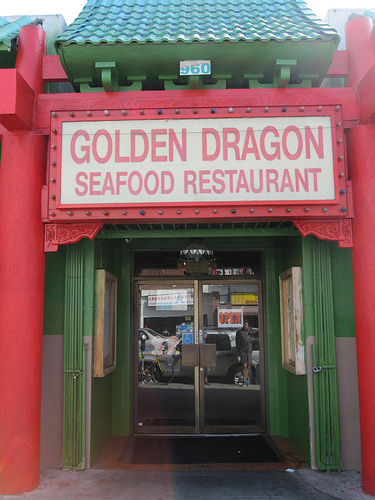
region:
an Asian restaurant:
[29, 75, 349, 301]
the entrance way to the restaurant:
[118, 255, 294, 470]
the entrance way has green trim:
[52, 207, 344, 439]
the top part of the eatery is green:
[52, 1, 362, 133]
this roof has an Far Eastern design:
[30, 8, 373, 172]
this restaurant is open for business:
[186, 287, 274, 366]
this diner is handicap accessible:
[138, 308, 228, 378]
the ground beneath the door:
[44, 449, 338, 498]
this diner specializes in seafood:
[66, 158, 338, 224]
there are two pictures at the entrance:
[87, 249, 314, 439]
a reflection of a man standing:
[233, 320, 254, 386]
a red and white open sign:
[217, 309, 245, 326]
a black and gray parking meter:
[139, 331, 147, 382]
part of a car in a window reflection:
[138, 328, 172, 350]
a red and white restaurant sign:
[46, 103, 349, 215]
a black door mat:
[126, 429, 285, 468]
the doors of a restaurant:
[137, 279, 270, 430]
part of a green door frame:
[305, 237, 343, 473]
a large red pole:
[0, 131, 60, 496]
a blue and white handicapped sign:
[180, 331, 193, 344]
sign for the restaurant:
[51, 114, 344, 210]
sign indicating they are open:
[217, 306, 251, 329]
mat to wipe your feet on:
[133, 435, 273, 463]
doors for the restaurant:
[135, 280, 269, 437]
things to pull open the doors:
[181, 345, 215, 367]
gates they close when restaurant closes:
[69, 238, 344, 489]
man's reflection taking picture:
[233, 323, 262, 394]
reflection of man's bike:
[137, 345, 182, 384]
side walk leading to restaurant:
[43, 470, 366, 498]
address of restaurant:
[171, 43, 221, 79]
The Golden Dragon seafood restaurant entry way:
[22, 111, 365, 460]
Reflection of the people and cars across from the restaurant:
[137, 308, 263, 390]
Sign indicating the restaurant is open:
[208, 300, 249, 330]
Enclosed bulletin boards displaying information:
[277, 257, 314, 389]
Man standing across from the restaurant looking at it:
[232, 311, 254, 386]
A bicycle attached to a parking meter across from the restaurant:
[133, 330, 181, 393]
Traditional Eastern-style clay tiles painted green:
[60, 5, 339, 40]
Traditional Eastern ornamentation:
[36, 216, 99, 258]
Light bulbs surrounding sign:
[45, 105, 348, 213]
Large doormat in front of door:
[106, 428, 290, 466]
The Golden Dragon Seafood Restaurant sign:
[45, 105, 350, 220]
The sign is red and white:
[38, 98, 361, 239]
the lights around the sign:
[55, 107, 355, 221]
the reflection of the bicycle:
[139, 346, 181, 392]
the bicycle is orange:
[141, 347, 175, 386]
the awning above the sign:
[47, 0, 338, 79]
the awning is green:
[62, 2, 352, 72]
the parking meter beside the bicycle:
[140, 333, 149, 390]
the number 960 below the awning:
[171, 54, 218, 78]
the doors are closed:
[129, 278, 272, 444]